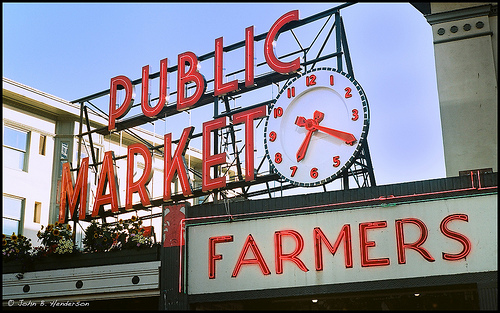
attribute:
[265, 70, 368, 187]
clock — red, white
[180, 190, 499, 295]
sign — red, neon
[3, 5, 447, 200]
sky — blue, clear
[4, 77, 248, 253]
building — decorative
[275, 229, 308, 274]
letter — neon, red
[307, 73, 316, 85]
numbers — red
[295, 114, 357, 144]
hand — red